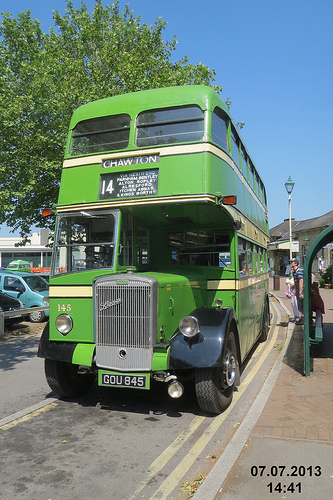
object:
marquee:
[98, 154, 159, 200]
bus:
[37, 85, 270, 416]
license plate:
[101, 373, 147, 388]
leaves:
[177, 478, 202, 499]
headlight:
[179, 315, 201, 338]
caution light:
[222, 196, 237, 205]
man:
[289, 257, 304, 324]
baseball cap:
[289, 257, 299, 266]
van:
[6, 259, 32, 272]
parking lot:
[0, 266, 50, 323]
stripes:
[207, 271, 270, 291]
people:
[284, 258, 325, 330]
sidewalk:
[186, 285, 333, 500]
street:
[0, 232, 333, 499]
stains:
[18, 396, 89, 482]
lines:
[131, 299, 281, 500]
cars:
[0, 271, 50, 323]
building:
[0, 229, 87, 277]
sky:
[157, 9, 332, 212]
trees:
[0, 0, 246, 285]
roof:
[268, 210, 333, 248]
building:
[265, 209, 333, 290]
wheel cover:
[169, 305, 241, 372]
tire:
[195, 321, 239, 415]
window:
[160, 229, 237, 265]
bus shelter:
[303, 226, 333, 377]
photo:
[0, 0, 333, 500]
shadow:
[43, 370, 218, 418]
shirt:
[292, 267, 305, 301]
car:
[0, 290, 25, 332]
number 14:
[102, 179, 114, 195]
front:
[36, 85, 240, 415]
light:
[55, 313, 74, 337]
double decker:
[37, 84, 270, 414]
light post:
[284, 174, 295, 292]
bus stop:
[302, 224, 333, 377]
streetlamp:
[284, 174, 295, 194]